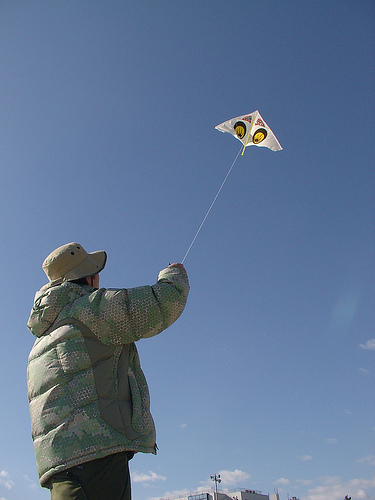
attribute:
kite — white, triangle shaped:
[212, 107, 283, 158]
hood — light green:
[29, 281, 83, 336]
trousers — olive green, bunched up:
[46, 449, 138, 498]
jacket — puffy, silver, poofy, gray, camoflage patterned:
[25, 262, 192, 490]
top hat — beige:
[40, 241, 109, 284]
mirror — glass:
[201, 491, 207, 499]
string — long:
[176, 146, 243, 267]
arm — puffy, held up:
[80, 263, 192, 345]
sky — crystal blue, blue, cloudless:
[0, 0, 374, 499]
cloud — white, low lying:
[128, 469, 168, 485]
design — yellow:
[232, 114, 269, 146]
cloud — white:
[201, 466, 256, 486]